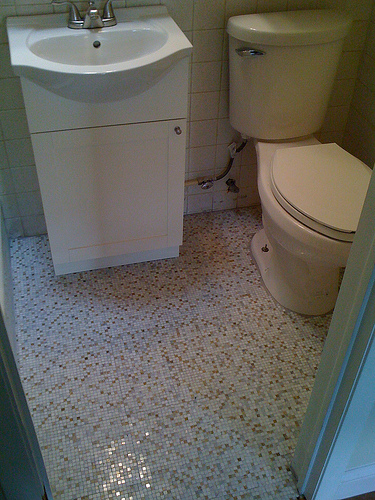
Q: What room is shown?
A: It is a bathroom.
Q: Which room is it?
A: It is a bathroom.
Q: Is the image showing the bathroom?
A: Yes, it is showing the bathroom.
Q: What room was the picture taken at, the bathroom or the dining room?
A: It was taken at the bathroom.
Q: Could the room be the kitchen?
A: No, it is the bathroom.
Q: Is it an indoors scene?
A: Yes, it is indoors.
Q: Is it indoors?
A: Yes, it is indoors.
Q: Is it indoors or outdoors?
A: It is indoors.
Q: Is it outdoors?
A: No, it is indoors.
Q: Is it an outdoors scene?
A: No, it is indoors.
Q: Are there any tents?
A: No, there are no tents.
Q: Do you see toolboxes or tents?
A: No, there are no tents or toolboxes.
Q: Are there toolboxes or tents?
A: No, there are no tents or toolboxes.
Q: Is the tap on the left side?
A: Yes, the tap is on the left of the image.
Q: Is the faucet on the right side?
A: No, the faucet is on the left of the image.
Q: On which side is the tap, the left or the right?
A: The tap is on the left of the image.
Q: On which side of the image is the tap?
A: The tap is on the left of the image.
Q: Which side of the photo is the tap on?
A: The tap is on the left of the image.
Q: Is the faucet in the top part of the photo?
A: Yes, the faucet is in the top of the image.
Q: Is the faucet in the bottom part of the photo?
A: No, the faucet is in the top of the image.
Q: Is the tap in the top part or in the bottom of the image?
A: The tap is in the top of the image.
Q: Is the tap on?
A: Yes, the tap is on.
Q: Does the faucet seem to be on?
A: Yes, the faucet is on.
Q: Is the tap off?
A: No, the tap is on.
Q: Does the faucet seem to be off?
A: No, the faucet is on.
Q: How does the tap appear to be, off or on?
A: The tap is on.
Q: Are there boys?
A: No, there are no boys.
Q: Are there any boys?
A: No, there are no boys.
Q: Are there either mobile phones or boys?
A: No, there are no boys or mobile phones.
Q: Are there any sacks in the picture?
A: No, there are no sacks.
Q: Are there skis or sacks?
A: No, there are no sacks or skis.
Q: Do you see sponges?
A: No, there are no sponges.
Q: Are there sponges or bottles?
A: No, there are no sponges or bottles.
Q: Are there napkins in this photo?
A: No, there are no napkins.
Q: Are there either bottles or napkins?
A: No, there are no napkins or bottles.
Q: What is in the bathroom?
A: The toilet is in the bathroom.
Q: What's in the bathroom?
A: The toilet is in the bathroom.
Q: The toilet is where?
A: The toilet is in the bathroom.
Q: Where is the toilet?
A: The toilet is in the bathroom.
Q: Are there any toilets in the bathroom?
A: Yes, there is a toilet in the bathroom.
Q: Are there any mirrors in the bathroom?
A: No, there is a toilet in the bathroom.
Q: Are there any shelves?
A: No, there are no shelves.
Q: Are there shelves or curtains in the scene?
A: No, there are no shelves or curtains.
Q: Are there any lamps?
A: No, there are no lamps.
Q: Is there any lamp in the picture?
A: No, there are no lamps.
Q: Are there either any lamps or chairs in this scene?
A: No, there are no lamps or chairs.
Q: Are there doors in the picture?
A: Yes, there is a door.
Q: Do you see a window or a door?
A: Yes, there is a door.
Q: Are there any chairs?
A: No, there are no chairs.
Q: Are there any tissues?
A: No, there are no tissues.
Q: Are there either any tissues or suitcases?
A: No, there are no tissues or suitcases.